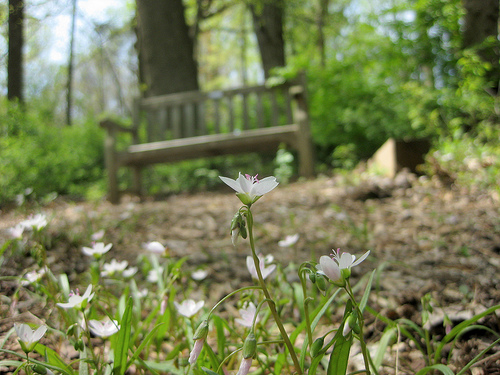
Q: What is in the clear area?
A: Bench.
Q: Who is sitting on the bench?
A: No one.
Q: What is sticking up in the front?
A: Flowers.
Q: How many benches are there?
A: One.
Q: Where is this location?
A: Park.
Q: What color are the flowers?
A: White.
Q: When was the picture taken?
A: Daytime.